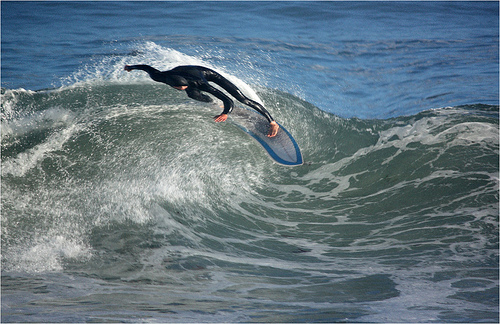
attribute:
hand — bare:
[216, 112, 229, 122]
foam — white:
[365, 259, 450, 322]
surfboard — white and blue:
[200, 83, 319, 175]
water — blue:
[4, 2, 499, 94]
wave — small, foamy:
[9, 33, 486, 256]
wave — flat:
[4, 39, 291, 276]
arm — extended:
[121, 63, 158, 81]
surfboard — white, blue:
[218, 100, 303, 166]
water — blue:
[311, 17, 483, 99]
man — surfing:
[115, 55, 292, 145]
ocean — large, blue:
[3, 0, 498, 323]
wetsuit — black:
[127, 65, 272, 122]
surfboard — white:
[229, 104, 306, 167]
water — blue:
[3, 2, 498, 321]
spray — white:
[137, 30, 175, 60]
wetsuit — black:
[126, 59, 278, 131]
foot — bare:
[265, 111, 280, 141]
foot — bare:
[209, 110, 229, 123]